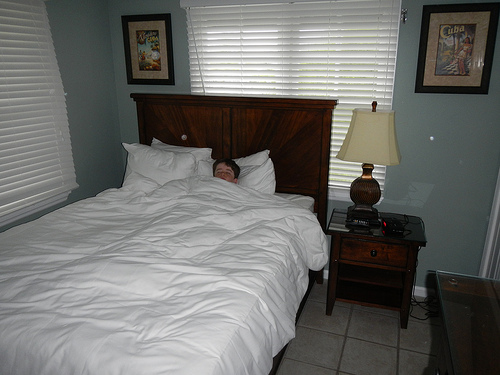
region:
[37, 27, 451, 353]
Picture is taken indoors.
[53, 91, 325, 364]
A boy is sleeping in the bed.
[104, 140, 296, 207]
The pillows are white.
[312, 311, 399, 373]
The floor is made of tile.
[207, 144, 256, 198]
The boy has short hair.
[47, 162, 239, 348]
The bed cover is white in color.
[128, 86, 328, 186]
The bed frame is made of wood.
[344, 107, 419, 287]
The lamp is turned off.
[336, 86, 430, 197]
The lampshade is ivory in color.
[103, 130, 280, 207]
Three pillows on the bed.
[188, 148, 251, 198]
the head of a young boy laying in a bed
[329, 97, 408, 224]
a lamp with a white shade on the bed side table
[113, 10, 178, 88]
a picture hanging on the wall behind the bed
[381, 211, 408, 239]
a small black alarm clock with red numbers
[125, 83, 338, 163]
a large dark brown headboard on the bed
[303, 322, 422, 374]
a light-colored tile floor in the room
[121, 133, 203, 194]
two fluffy white pillows in the bed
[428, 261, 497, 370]
the top of a glass covered nightstand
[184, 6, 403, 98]
a window covered with white mini blinds behind the bed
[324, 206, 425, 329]
a small dark brown wooden bedside table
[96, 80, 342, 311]
small boy in large bed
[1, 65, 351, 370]
bed with tall headboard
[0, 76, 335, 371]
bed with white sheets and blanket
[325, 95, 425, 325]
nightstand with lamp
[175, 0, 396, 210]
large window with white blinds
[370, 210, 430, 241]
digital alarm clock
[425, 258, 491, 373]
glass countertop on wooden table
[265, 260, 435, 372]
brown tile floor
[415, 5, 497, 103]
picture with black frame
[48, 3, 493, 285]
grey-blue walls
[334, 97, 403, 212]
lamp with white shade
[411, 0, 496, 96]
Cuba picture hanging on wall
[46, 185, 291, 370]
fluffy white comforter on bed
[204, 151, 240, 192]
boy sleeping in bed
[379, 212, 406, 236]
alarm clock on night stand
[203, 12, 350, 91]
shades on windows drawn shut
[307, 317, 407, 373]
beige tile floor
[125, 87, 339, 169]
wooden headboard at top of bed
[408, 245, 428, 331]
electrical cord plugged into wall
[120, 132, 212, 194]
fluffy white pillows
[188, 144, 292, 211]
A boy asleep in bed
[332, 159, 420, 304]
A wooden nightstand with a lamp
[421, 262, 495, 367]
A dresser with a glass protective layer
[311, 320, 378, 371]
A tile floor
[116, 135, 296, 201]
Four fluffy white pillows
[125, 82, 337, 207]
A wooden bed frame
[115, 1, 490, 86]
Two pictures framing a window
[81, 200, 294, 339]
A white comforter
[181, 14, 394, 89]
A window covered with blinds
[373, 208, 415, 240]
An alarm clock with glowing red numbers